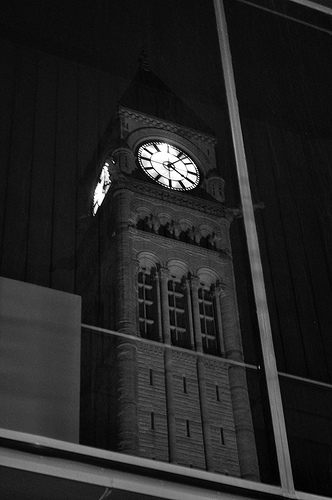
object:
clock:
[130, 124, 205, 195]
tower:
[75, 53, 261, 481]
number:
[166, 141, 171, 155]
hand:
[171, 165, 196, 184]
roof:
[81, 86, 232, 198]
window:
[131, 243, 162, 346]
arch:
[130, 199, 156, 238]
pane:
[144, 271, 156, 288]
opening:
[196, 222, 221, 255]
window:
[161, 265, 194, 355]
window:
[194, 262, 223, 354]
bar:
[80, 323, 262, 371]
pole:
[213, 0, 293, 491]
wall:
[4, 1, 98, 291]